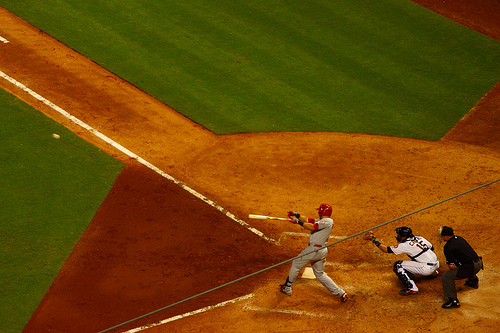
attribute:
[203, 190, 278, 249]
line — white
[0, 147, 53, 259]
grass — green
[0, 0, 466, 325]
baseball field — large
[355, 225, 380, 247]
catcher's mitt — brown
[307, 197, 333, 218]
helmet — red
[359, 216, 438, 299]
helmet — black, catcher's helmet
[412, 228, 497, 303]
umpire — crouched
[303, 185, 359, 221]
helmet — red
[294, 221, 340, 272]
uniform — grey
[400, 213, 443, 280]
uniform — white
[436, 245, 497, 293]
uniform — black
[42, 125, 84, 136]
ball — white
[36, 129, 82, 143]
ball — white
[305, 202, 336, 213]
helmet — red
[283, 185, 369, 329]
player — playing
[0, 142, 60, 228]
grass — green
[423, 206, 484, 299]
uniform — black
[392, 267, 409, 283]
protector — black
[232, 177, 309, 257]
bat — wooden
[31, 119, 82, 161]
ball — white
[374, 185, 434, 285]
catcher — crouched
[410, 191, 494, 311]
umpire — crouched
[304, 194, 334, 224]
helmet — red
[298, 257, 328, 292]
home plate — white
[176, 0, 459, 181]
grass — green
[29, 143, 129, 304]
grass — green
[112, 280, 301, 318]
chalk — white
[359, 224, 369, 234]
mitt — brown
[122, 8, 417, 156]
field — baseball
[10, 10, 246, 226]
field — ball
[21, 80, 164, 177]
stripes — white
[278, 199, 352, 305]
player — baseball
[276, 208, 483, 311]
people — three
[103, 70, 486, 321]
game — ball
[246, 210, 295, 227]
bat — baseball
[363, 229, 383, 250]
mitt — brown, catcher's